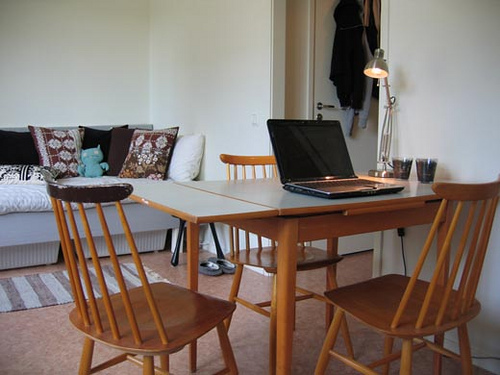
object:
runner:
[0, 263, 173, 314]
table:
[128, 177, 454, 375]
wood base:
[215, 201, 449, 243]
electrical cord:
[396, 228, 406, 276]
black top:
[47, 183, 134, 203]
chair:
[49, 182, 235, 374]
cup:
[415, 158, 438, 184]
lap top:
[267, 119, 404, 199]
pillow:
[119, 127, 179, 178]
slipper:
[198, 259, 222, 275]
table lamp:
[363, 49, 396, 177]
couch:
[1, 126, 205, 270]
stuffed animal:
[77, 144, 108, 177]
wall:
[148, 0, 273, 268]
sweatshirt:
[330, 2, 367, 109]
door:
[313, 0, 381, 255]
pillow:
[28, 126, 84, 179]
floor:
[0, 247, 499, 374]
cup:
[392, 155, 412, 178]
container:
[0, 240, 60, 269]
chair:
[312, 178, 500, 374]